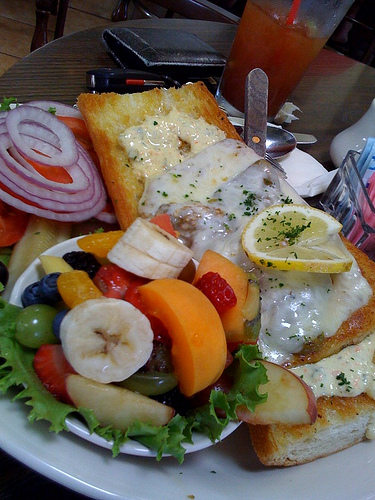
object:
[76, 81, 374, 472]
fish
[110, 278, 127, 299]
sauce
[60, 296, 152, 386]
banana slice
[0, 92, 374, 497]
plate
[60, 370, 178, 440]
slice of fruit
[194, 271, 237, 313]
berry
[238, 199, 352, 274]
lemon wedge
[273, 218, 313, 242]
parsley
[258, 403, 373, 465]
cut edge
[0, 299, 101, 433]
lettuce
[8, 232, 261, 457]
bowl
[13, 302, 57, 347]
grape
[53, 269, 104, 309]
orange slice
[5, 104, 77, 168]
onion slice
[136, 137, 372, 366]
cheese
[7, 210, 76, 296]
pickle spear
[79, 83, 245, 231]
bread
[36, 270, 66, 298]
blueberries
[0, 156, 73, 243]
tomato slice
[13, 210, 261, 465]
fruit salad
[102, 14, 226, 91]
wallet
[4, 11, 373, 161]
table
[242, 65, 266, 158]
wooden utensil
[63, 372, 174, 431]
food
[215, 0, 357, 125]
glass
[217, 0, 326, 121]
orange drink